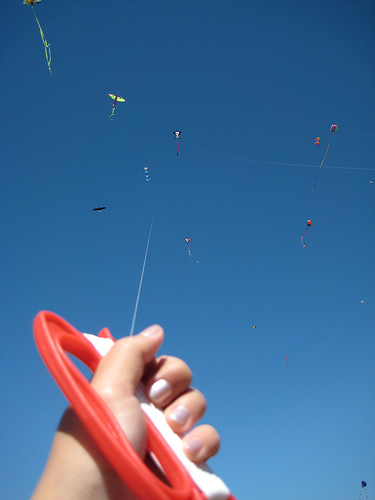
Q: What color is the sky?
A: Blue.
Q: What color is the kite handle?
A: Red.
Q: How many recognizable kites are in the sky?
A: 10.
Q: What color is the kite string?
A: White.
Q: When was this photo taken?
A: Daytime.